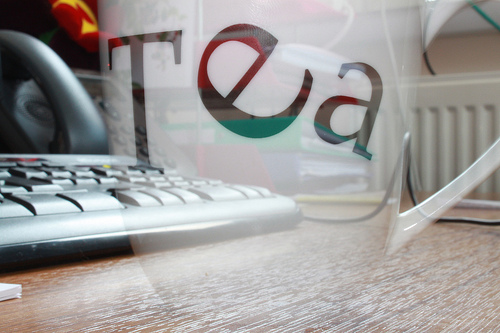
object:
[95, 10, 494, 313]
glare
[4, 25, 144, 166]
phone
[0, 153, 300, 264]
computer keyboard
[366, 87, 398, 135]
ground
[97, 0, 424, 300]
black tea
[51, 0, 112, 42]
object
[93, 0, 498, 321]
cup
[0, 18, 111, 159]
giraffe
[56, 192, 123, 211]
button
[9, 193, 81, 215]
button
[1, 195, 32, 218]
button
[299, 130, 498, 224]
wire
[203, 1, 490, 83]
moulding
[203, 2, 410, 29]
window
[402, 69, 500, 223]
ac vent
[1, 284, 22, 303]
papers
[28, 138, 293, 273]
windows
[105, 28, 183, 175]
letter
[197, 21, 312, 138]
letter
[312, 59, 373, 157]
letter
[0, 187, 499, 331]
desk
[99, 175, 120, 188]
key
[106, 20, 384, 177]
word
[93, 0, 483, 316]
ghost image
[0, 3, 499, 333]
image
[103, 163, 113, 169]
dial pad